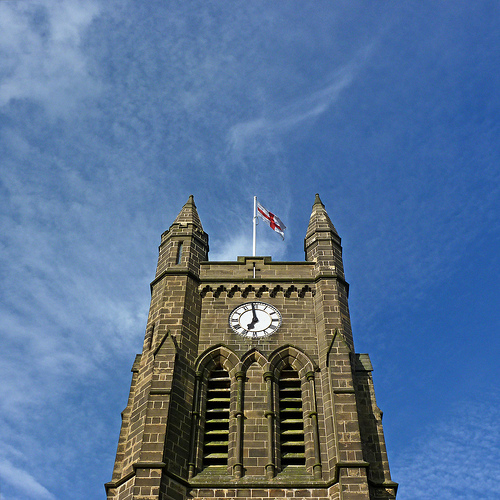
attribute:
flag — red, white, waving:
[254, 197, 286, 242]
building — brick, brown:
[105, 194, 401, 499]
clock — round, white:
[228, 301, 280, 339]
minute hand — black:
[250, 303, 259, 323]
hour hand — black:
[246, 319, 258, 333]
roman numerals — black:
[232, 305, 279, 337]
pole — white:
[251, 194, 258, 257]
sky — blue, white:
[0, 0, 497, 499]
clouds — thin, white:
[1, 2, 400, 499]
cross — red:
[258, 208, 283, 235]